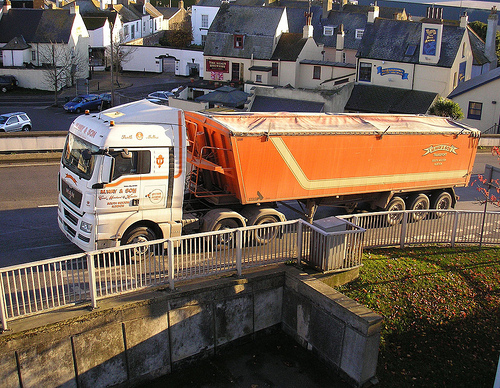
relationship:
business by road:
[363, 40, 454, 125] [48, 112, 74, 132]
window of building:
[302, 59, 328, 82] [208, 29, 340, 100]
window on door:
[233, 66, 241, 71] [235, 59, 240, 87]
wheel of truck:
[440, 191, 462, 219] [66, 115, 499, 208]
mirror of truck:
[100, 145, 124, 195] [66, 115, 499, 208]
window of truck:
[65, 136, 97, 174] [66, 115, 499, 208]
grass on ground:
[380, 257, 436, 313] [405, 253, 494, 322]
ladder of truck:
[185, 124, 208, 201] [66, 115, 499, 208]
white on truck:
[260, 147, 310, 186] [66, 115, 499, 208]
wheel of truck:
[416, 195, 427, 223] [66, 115, 499, 208]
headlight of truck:
[70, 211, 116, 244] [66, 115, 499, 208]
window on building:
[123, 22, 134, 40] [115, 1, 144, 42]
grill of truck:
[62, 202, 95, 225] [66, 115, 499, 208]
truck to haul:
[66, 115, 499, 208] [241, 124, 416, 126]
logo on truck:
[417, 138, 462, 160] [66, 115, 499, 208]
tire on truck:
[381, 201, 414, 220] [66, 115, 499, 208]